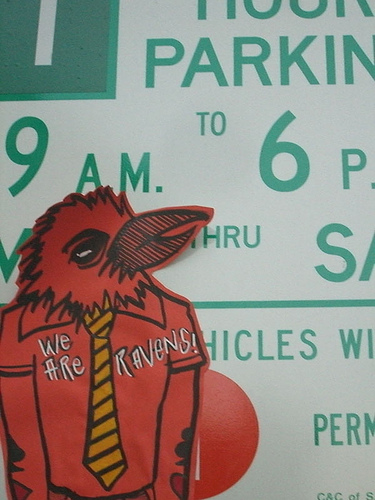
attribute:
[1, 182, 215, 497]
bird mascot — red, wooden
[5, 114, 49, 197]
number nine — green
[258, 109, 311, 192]
number six — green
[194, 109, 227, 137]
letters — green, spell "to"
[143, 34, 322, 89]
letters — spell "park", green